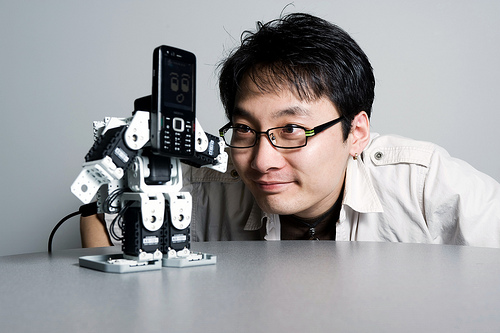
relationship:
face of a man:
[222, 81, 347, 213] [74, 26, 499, 248]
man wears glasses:
[74, 26, 499, 248] [215, 124, 324, 151]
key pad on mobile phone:
[164, 128, 192, 155] [152, 42, 195, 162]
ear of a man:
[351, 112, 371, 157] [74, 26, 499, 248]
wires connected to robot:
[101, 186, 130, 246] [75, 46, 231, 272]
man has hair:
[74, 26, 499, 248] [207, 19, 388, 129]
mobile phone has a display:
[152, 42, 195, 162] [162, 60, 197, 107]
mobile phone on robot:
[152, 42, 195, 162] [75, 46, 231, 272]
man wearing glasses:
[74, 26, 499, 248] [215, 124, 324, 151]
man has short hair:
[74, 26, 499, 248] [207, 19, 388, 129]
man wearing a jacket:
[74, 26, 499, 248] [98, 138, 498, 239]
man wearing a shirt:
[74, 26, 499, 248] [275, 217, 337, 247]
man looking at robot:
[74, 26, 499, 248] [75, 46, 231, 272]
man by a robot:
[74, 26, 499, 248] [75, 46, 231, 272]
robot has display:
[75, 46, 231, 272] [162, 60, 197, 107]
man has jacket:
[74, 26, 499, 248] [98, 138, 498, 239]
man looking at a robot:
[74, 26, 499, 248] [75, 46, 231, 272]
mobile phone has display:
[152, 42, 195, 162] [162, 60, 197, 107]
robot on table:
[75, 46, 231, 272] [5, 239, 499, 327]